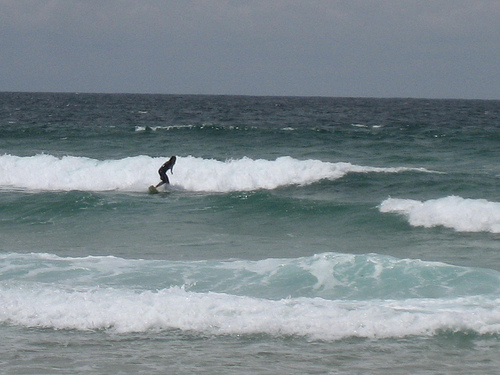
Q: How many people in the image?
A: One.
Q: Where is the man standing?
A: On a surfboard.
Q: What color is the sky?
A: Gray.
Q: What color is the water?
A: Blue.